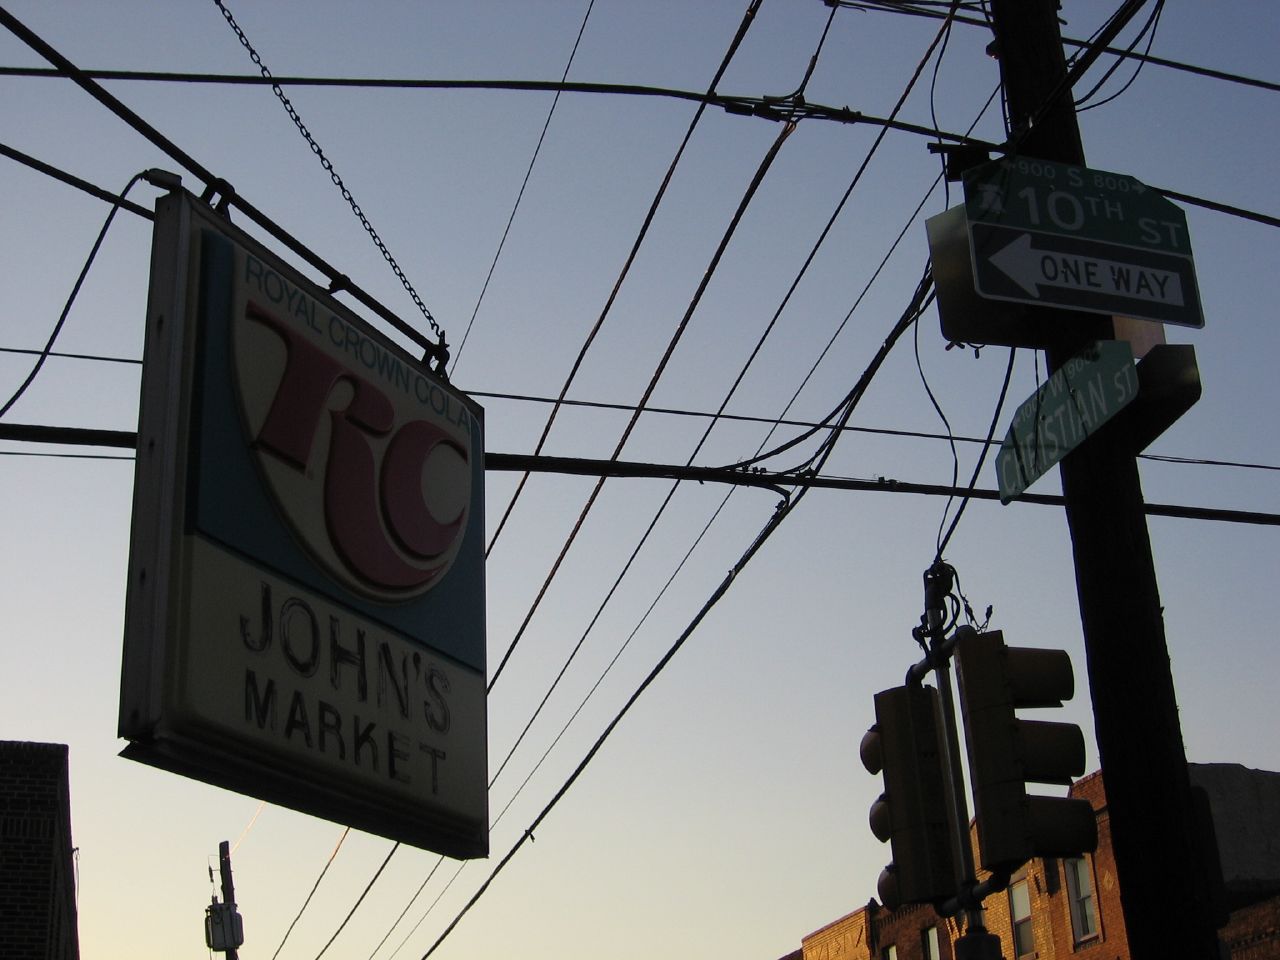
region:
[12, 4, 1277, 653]
suspended utility cables on a pole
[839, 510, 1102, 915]
a suspended traffic signal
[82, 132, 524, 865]
a white, red and blue business sign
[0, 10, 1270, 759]
an expanse of clear blue sky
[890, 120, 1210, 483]
street signs on a pole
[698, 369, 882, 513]
a bend in a utility cable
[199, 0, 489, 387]
a chain connected to the top of a sign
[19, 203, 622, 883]
sign above the land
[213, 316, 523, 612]
letters on the sign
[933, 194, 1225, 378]
black and white sign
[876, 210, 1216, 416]
arrow pointing to the left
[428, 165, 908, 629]
wires above the ground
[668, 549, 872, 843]
sky with no clouds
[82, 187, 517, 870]
store sign hanging from pole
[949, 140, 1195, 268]
street sign is green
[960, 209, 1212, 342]
second sign is black and white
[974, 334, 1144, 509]
bottom sign is green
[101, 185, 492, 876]
A RC cola sign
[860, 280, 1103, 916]
traffic light hanging from wires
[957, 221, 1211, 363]
A black and white sign.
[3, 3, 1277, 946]
Powerlines running from poles.